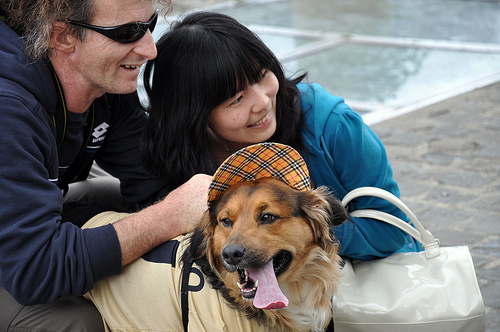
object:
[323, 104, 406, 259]
arm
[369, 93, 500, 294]
path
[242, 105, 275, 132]
smile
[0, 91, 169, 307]
arm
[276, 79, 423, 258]
sweater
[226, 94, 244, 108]
eye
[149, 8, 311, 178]
hair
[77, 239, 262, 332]
clothes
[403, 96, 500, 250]
flooring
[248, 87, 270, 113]
nose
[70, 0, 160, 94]
face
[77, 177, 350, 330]
dog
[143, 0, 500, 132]
window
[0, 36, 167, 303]
jacket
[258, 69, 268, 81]
eye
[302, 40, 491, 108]
surface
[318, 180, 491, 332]
purse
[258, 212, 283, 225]
eyes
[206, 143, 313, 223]
hat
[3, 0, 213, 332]
man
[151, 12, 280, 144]
head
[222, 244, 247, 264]
nose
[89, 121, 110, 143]
logo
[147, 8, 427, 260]
woman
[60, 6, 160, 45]
sun glasses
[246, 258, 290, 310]
tongue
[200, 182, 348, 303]
dog's head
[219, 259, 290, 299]
mouth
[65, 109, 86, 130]
man's shirt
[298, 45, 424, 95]
reflections